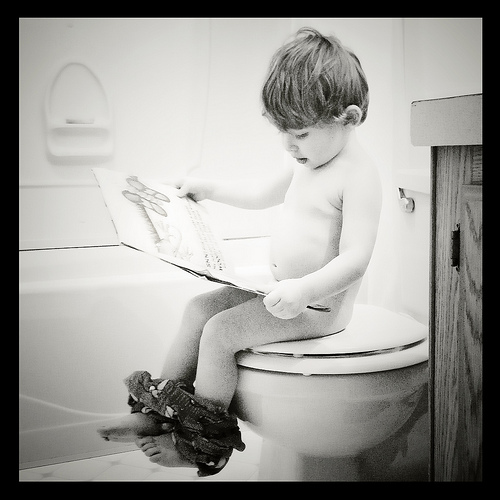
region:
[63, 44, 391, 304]
a little boy reading a book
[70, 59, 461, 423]
a little boy reading a book on a toilet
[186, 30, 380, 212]
a little boy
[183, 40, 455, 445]
a little boy on a toilet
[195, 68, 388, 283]
a little boy with no shirt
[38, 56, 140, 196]
a white soap container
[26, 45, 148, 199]
a soap holder on the wall of a shower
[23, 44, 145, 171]
a soap holder on the wall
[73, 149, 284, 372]
a childrens book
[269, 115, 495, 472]
a white toilet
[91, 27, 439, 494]
little boy sitting on the toilet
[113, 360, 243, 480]
little boy's pajama pants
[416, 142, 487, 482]
deep grained wooden bathroom cabinet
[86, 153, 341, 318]
large children's book being held by a boy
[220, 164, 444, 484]
shiny white porcelain toilet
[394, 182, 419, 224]
shiny silver toilet flush handle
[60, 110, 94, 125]
used white bar of soap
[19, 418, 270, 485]
white linoleum flooring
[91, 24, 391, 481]
little boy reading a book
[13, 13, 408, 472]
white fiberglass bathtub shower combination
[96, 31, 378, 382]
little boy is sitting on the lid of the potty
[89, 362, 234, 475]
pajama pants down to his ankles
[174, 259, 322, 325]
paper in his hands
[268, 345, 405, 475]
toilet in the bathroom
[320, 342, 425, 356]
lid on the toilet is down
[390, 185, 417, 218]
handle on the toilet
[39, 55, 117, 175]
build in soap shelf in the tub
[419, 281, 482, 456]
cabinet by the toilet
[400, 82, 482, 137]
edge of the counter top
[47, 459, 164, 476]
linoleum floor in the bathroom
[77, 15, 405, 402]
a toddler sitting on toliet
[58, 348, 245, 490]
pants down by feet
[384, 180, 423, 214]
a silver handle on toliet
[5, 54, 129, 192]
a bar of soap in the tub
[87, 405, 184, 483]
little bare feet of boy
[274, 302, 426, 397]
the toliet lid is closed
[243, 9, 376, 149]
the toddler has long hair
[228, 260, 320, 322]
a little hand holding a book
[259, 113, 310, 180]
the child's face looking down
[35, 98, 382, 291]
a toddler reading a book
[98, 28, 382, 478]
kid on the toilet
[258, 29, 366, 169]
kid is looking down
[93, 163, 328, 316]
kid is holding a book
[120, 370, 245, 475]
kid's pants are down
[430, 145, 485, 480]
the cabinet is made of wood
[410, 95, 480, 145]
top part of the cabinet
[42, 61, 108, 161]
soap holder on the wall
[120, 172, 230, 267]
drawings and text on the page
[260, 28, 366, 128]
the hair is long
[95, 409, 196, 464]
kid has bare feet